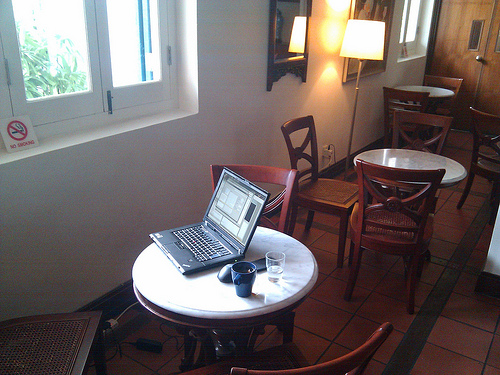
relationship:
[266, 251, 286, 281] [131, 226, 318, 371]
glass on table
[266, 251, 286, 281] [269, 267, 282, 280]
glass has water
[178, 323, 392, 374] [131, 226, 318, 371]
chair in front of table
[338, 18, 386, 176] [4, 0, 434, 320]
lamp close to wall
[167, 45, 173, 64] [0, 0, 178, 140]
hinge of window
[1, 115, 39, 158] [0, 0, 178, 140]
no smoking sign on window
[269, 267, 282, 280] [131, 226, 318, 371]
water on table